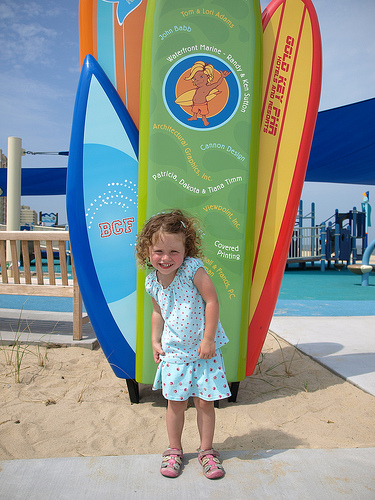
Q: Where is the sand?
A: On the ground.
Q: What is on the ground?
A: Sand.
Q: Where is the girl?
A: In front of the surfboards.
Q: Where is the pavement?
A: Under the girl.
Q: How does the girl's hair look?
A: Short and brown.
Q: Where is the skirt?
A: On the girl.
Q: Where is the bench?
A: Behind the surfboards.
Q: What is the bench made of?
A: Wood.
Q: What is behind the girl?
A: Surfboards.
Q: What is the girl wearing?
A: A blue dress with red dots.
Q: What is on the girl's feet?
A: Pink shoes.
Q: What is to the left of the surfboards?
A: A wooden bench.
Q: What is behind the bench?
A: Swimming pool.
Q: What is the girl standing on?
A: Sand.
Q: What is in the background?
A: A playground.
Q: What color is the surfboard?
A: Green.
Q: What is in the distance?
A: A playground.